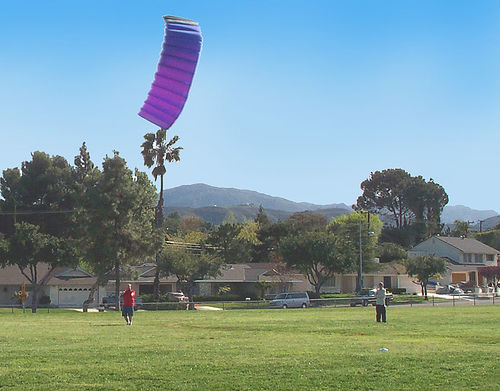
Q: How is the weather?
A: It is cloudless.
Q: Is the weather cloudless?
A: Yes, it is cloudless.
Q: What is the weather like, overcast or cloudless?
A: It is cloudless.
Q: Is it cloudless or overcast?
A: It is cloudless.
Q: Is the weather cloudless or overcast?
A: It is cloudless.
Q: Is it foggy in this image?
A: No, it is cloudless.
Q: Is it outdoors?
A: Yes, it is outdoors.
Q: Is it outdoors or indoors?
A: It is outdoors.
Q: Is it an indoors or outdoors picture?
A: It is outdoors.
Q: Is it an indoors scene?
A: No, it is outdoors.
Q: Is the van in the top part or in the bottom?
A: The van is in the bottom of the image.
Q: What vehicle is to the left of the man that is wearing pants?
A: The vehicle is a van.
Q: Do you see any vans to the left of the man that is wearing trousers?
A: Yes, there is a van to the left of the man.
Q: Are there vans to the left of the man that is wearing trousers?
A: Yes, there is a van to the left of the man.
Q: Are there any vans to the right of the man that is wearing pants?
A: No, the van is to the left of the man.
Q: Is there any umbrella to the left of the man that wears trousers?
A: No, there is a van to the left of the man.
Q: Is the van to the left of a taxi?
A: No, the van is to the left of the man.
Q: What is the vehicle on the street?
A: The vehicle is a van.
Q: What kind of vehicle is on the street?
A: The vehicle is a van.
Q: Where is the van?
A: The van is on the street.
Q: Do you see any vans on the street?
A: Yes, there is a van on the street.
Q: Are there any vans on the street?
A: Yes, there is a van on the street.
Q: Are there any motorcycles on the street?
A: No, there is a van on the street.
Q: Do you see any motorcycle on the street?
A: No, there is a van on the street.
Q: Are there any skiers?
A: No, there are no skiers.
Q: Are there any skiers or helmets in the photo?
A: No, there are no skiers or helmets.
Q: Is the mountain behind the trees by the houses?
A: Yes, the mountain is behind the trees.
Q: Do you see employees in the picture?
A: No, there are no employees.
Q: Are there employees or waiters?
A: No, there are no employees or waiters.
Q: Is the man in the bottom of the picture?
A: Yes, the man is in the bottom of the image.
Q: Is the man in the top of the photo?
A: No, the man is in the bottom of the image.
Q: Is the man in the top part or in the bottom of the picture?
A: The man is in the bottom of the image.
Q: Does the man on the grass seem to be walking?
A: Yes, the man is walking.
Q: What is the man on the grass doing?
A: The man is walking.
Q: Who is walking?
A: The man is walking.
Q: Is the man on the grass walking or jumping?
A: The man is walking.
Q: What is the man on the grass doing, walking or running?
A: The man is walking.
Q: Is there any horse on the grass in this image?
A: No, there is a man on the grass.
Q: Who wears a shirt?
A: The man wears a shirt.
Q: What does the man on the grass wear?
A: The man wears a shirt.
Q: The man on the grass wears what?
A: The man wears a shirt.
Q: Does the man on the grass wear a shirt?
A: Yes, the man wears a shirt.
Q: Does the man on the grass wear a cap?
A: No, the man wears a shirt.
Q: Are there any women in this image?
A: No, there are no women.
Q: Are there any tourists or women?
A: No, there are no women or tourists.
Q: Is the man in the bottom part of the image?
A: Yes, the man is in the bottom of the image.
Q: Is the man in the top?
A: No, the man is in the bottom of the image.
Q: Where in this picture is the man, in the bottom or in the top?
A: The man is in the bottom of the image.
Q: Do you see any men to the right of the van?
A: Yes, there is a man to the right of the van.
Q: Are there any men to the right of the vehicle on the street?
A: Yes, there is a man to the right of the van.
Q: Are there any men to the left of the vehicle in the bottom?
A: No, the man is to the right of the van.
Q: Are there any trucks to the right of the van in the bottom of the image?
A: No, there is a man to the right of the van.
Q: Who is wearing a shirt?
A: The man is wearing a shirt.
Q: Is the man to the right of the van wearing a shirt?
A: Yes, the man is wearing a shirt.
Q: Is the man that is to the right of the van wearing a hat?
A: No, the man is wearing a shirt.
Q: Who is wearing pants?
A: The man is wearing pants.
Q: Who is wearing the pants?
A: The man is wearing pants.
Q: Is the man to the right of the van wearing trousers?
A: Yes, the man is wearing trousers.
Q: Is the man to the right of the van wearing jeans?
A: No, the man is wearing trousers.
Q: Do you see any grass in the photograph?
A: Yes, there is grass.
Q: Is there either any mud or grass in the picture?
A: Yes, there is grass.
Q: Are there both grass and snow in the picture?
A: No, there is grass but no snow.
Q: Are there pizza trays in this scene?
A: No, there are no pizza trays.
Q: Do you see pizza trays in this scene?
A: No, there are no pizza trays.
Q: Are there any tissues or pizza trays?
A: No, there are no pizza trays or tissues.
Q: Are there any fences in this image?
A: No, there are no fences.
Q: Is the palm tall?
A: Yes, the palm is tall.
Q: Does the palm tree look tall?
A: Yes, the palm tree is tall.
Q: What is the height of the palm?
A: The palm is tall.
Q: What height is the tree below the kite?
A: The palm is tall.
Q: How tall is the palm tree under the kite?
A: The palm is tall.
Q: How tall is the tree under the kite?
A: The palm is tall.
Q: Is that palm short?
A: No, the palm is tall.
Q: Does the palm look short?
A: No, the palm is tall.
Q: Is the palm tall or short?
A: The palm is tall.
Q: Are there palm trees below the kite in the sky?
A: Yes, there is a palm tree below the kite.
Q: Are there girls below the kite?
A: No, there is a palm tree below the kite.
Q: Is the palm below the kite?
A: Yes, the palm is below the kite.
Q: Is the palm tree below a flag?
A: No, the palm tree is below the kite.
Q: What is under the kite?
A: The palm tree is under the kite.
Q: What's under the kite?
A: The palm tree is under the kite.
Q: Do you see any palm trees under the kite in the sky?
A: Yes, there is a palm tree under the kite.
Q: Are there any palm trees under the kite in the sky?
A: Yes, there is a palm tree under the kite.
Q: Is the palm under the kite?
A: Yes, the palm is under the kite.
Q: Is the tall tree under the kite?
A: Yes, the palm is under the kite.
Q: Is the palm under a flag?
A: No, the palm is under the kite.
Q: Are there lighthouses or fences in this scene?
A: No, there are no fences or lighthouses.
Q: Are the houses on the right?
A: Yes, the houses are on the right of the image.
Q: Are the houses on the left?
A: No, the houses are on the right of the image.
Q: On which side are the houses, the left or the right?
A: The houses are on the right of the image.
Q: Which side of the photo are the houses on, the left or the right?
A: The houses are on the right of the image.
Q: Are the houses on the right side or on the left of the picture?
A: The houses are on the right of the image.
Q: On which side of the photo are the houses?
A: The houses are on the right of the image.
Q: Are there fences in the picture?
A: No, there are no fences.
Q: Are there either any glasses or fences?
A: No, there are no fences or glasses.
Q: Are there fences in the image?
A: No, there are no fences.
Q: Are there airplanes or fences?
A: No, there are no fences or airplanes.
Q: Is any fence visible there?
A: No, there are no fences.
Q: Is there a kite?
A: Yes, there is a kite.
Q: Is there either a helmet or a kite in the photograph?
A: Yes, there is a kite.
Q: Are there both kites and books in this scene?
A: No, there is a kite but no books.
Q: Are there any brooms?
A: No, there are no brooms.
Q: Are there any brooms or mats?
A: No, there are no brooms or mats.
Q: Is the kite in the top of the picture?
A: Yes, the kite is in the top of the image.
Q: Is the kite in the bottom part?
A: No, the kite is in the top of the image.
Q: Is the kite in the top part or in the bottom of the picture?
A: The kite is in the top of the image.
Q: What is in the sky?
A: The kite is in the sky.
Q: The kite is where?
A: The kite is in the sky.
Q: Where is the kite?
A: The kite is in the sky.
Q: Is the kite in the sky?
A: Yes, the kite is in the sky.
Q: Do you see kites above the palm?
A: Yes, there is a kite above the palm.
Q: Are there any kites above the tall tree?
A: Yes, there is a kite above the palm.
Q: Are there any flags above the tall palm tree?
A: No, there is a kite above the palm.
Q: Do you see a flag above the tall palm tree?
A: No, there is a kite above the palm.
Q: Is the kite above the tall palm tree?
A: Yes, the kite is above the palm tree.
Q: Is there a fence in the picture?
A: No, there are no fences.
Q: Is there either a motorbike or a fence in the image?
A: No, there are no fences or motorcycles.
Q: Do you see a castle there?
A: No, there are no castles.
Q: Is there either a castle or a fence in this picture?
A: No, there are no castles or fences.